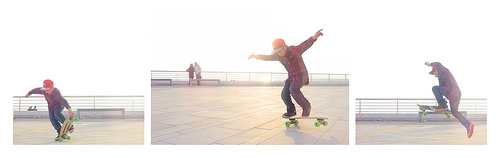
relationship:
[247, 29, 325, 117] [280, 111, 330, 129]
boy on skateboard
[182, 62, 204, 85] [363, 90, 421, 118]
couple on fence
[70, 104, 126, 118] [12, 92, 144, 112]
bench near gate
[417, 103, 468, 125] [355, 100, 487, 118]
bench near gate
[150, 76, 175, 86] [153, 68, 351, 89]
bench near gate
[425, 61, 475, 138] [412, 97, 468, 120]
boy on skate board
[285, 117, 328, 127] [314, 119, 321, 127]
skate board has green wheel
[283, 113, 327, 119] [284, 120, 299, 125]
skate board has green wheel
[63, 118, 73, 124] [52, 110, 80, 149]
wheel on skateboard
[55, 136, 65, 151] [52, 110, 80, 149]
wheel on skateboard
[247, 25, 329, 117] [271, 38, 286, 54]
boy has cap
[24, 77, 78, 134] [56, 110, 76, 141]
boy has skateboard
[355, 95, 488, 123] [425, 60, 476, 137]
fence behind boy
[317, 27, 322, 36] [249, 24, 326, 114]
finger of a man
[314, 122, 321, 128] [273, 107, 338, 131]
green wheel of a skateboard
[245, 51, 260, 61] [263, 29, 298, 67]
hand of a man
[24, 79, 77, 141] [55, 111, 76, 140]
boy on a skateboard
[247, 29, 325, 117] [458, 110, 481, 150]
boy on a skateboard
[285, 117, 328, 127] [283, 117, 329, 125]
skate board with green wheels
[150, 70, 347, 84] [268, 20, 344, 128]
fence behind person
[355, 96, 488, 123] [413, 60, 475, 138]
fence behind person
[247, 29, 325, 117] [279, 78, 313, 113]
boy has jeans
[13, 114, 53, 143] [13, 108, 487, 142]
line on concrete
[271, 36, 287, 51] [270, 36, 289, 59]
cap on head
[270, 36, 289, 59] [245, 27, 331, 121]
head on man